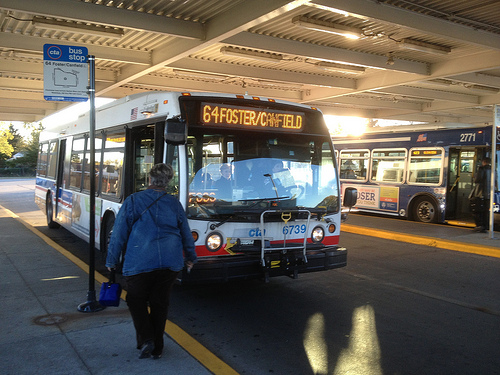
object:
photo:
[0, 1, 500, 374]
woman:
[99, 163, 195, 360]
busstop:
[40, 41, 104, 313]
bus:
[34, 90, 358, 288]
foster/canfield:
[202, 102, 305, 129]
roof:
[4, 2, 498, 126]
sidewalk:
[2, 209, 236, 375]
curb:
[18, 240, 230, 375]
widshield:
[191, 129, 333, 211]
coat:
[105, 185, 200, 277]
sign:
[42, 43, 95, 103]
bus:
[334, 125, 500, 230]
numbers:
[459, 132, 475, 143]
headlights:
[311, 225, 327, 244]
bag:
[98, 280, 122, 307]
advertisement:
[341, 185, 401, 216]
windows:
[40, 131, 125, 194]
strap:
[135, 191, 169, 221]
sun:
[345, 114, 368, 138]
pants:
[125, 266, 181, 357]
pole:
[89, 52, 96, 312]